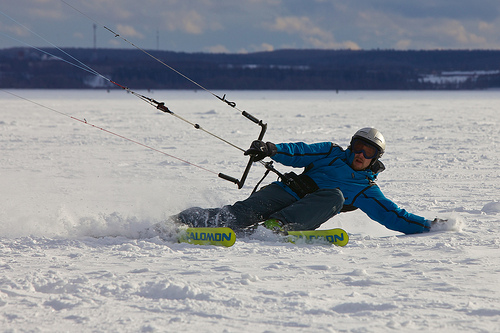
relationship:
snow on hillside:
[0, 88, 500, 333] [0, 88, 498, 330]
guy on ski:
[158, 122, 438, 258] [260, 219, 367, 254]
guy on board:
[158, 122, 438, 258] [178, 227, 237, 248]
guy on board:
[138, 127, 449, 249] [178, 227, 237, 248]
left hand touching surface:
[428, 215, 455, 235] [394, 238, 466, 284]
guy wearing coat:
[138, 127, 449, 249] [237, 116, 407, 233]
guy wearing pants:
[138, 127, 449, 249] [203, 174, 339, 225]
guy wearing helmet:
[138, 127, 449, 249] [354, 127, 386, 152]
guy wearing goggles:
[138, 127, 449, 249] [349, 137, 380, 162]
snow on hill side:
[0, 88, 500, 333] [77, 146, 155, 198]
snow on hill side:
[0, 88, 500, 333] [1, 85, 499, 331]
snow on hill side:
[6, 232, 498, 329] [1, 85, 499, 331]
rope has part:
[0, 87, 220, 176] [156, 146, 182, 161]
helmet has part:
[350, 126, 385, 161] [359, 126, 369, 136]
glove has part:
[242, 138, 277, 165] [262, 141, 271, 164]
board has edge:
[134, 219, 239, 249] [195, 226, 205, 242]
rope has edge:
[0, 3, 255, 161] [208, 88, 233, 104]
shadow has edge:
[357, 139, 369, 161] [346, 137, 362, 151]